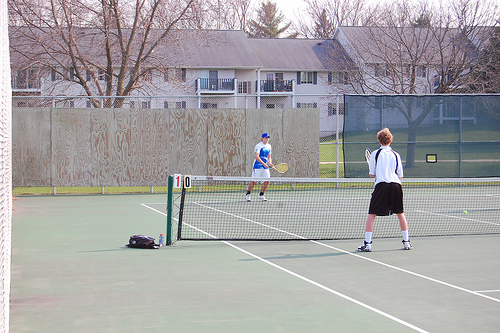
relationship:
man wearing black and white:
[355, 126, 414, 251] [367, 145, 405, 217]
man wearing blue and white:
[243, 131, 289, 201] [250, 140, 272, 185]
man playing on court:
[355, 126, 414, 251] [11, 185, 498, 331]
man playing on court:
[243, 131, 289, 201] [11, 185, 498, 331]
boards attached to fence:
[13, 106, 319, 188] [13, 94, 499, 197]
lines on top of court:
[141, 192, 498, 332] [11, 185, 498, 331]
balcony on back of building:
[195, 74, 237, 96] [7, 24, 499, 140]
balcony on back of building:
[252, 80, 294, 97] [7, 24, 499, 140]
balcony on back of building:
[10, 76, 45, 93] [7, 24, 499, 140]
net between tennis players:
[162, 172, 498, 244] [244, 126, 412, 254]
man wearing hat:
[243, 131, 289, 201] [260, 130, 270, 138]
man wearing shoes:
[355, 126, 414, 251] [358, 238, 414, 252]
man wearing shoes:
[243, 131, 289, 201] [243, 191, 268, 203]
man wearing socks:
[355, 126, 414, 251] [363, 227, 408, 241]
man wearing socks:
[243, 131, 289, 201] [245, 187, 266, 195]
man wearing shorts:
[355, 126, 414, 251] [367, 179, 405, 217]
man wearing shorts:
[243, 131, 289, 201] [250, 167, 272, 184]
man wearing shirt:
[355, 126, 414, 251] [367, 143, 403, 185]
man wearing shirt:
[243, 131, 289, 201] [251, 142, 273, 170]